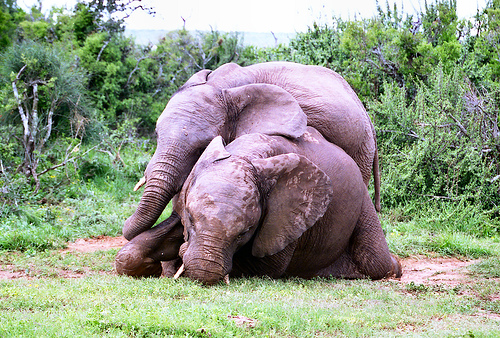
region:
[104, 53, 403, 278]
two elephants playing with each other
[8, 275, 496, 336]
the grass on the ground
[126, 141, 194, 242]
the trunk of the elephant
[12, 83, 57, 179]
a bare tree off to the side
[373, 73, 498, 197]
a green bush next to the elephants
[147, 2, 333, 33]
a patch of the sunny sky above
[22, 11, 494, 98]
assorted green trees and bushes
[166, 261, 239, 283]
the tusks on the elephant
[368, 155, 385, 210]
the tail on the elephant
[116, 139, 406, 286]
the elephant on the bottom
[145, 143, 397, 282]
The elephant is grey.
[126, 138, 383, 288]
The elephant is muddy.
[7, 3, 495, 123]
The trees are leafy.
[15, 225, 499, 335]
The ground is muddy and grassy.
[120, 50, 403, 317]
The two elephants are on the ground.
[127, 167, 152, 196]
The tusk is white.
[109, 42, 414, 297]
One elephant is on another elephant.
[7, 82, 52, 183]
The branches are brown.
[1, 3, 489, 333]
The sun is shining.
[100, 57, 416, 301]
The elephants have big ears.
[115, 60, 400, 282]
two large elephants cuddling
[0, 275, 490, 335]
grass on the ground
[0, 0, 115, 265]
forest area and a tree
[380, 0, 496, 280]
forest area and some trees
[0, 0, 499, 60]
very green forest and trees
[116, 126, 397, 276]
elephant lying down on ground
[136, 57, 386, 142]
elephant lying down resting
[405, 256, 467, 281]
brown dirt area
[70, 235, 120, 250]
brown dirt ground area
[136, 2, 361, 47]
pale blue horizon line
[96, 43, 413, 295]
two elephants are playing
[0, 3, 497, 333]
elephants are in a forest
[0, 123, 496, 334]
an elephant lying on green grass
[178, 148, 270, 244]
head has discolored skin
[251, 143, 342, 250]
ear has discolored skin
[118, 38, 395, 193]
an elephant on top of elephant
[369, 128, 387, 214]
tail of elephant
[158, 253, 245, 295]
tasks of elephant on the grass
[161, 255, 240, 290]
two white tusks of elephant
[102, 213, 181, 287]
leg of elephant is bend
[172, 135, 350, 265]
the elephant is on the ground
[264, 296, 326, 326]
the grass is green in color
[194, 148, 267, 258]
the elephant has white blotches on its head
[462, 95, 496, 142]
the branch has no leaves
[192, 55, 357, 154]
the elephant is sitting on the other elephant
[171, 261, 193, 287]
the tusk is white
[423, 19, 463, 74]
the tree has leaves on it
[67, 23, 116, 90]
the bush has leaves on it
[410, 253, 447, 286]
the dirt is brown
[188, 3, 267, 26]
the sky looks hazy